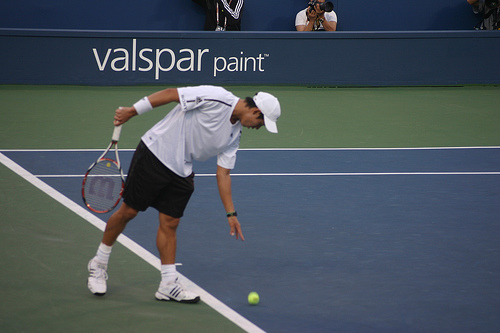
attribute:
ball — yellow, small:
[245, 292, 261, 304]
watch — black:
[227, 214, 238, 219]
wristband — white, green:
[126, 97, 157, 117]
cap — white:
[251, 89, 282, 135]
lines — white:
[6, 146, 498, 332]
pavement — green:
[1, 87, 498, 331]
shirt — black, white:
[137, 84, 238, 178]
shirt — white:
[140, 87, 242, 179]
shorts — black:
[121, 137, 195, 216]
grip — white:
[109, 106, 125, 146]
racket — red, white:
[80, 105, 124, 215]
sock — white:
[89, 242, 114, 265]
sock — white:
[161, 258, 178, 284]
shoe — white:
[83, 256, 108, 296]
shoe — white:
[156, 282, 200, 305]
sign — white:
[89, 35, 277, 80]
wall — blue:
[8, 32, 498, 86]